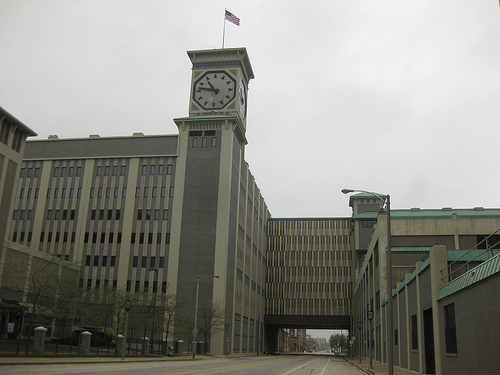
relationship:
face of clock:
[192, 72, 236, 112] [188, 49, 248, 131]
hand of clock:
[197, 86, 220, 93] [188, 49, 248, 131]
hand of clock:
[207, 81, 218, 94] [188, 49, 248, 131]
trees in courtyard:
[19, 256, 226, 354] [4, 332, 186, 364]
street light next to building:
[191, 273, 221, 361] [25, 139, 269, 357]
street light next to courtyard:
[191, 273, 221, 361] [4, 332, 186, 364]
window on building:
[137, 209, 143, 220] [25, 139, 269, 357]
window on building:
[139, 232, 146, 246] [25, 139, 269, 357]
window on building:
[148, 233, 154, 245] [25, 139, 269, 357]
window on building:
[155, 209, 161, 220] [25, 139, 269, 357]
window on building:
[143, 186, 149, 197] [25, 139, 269, 357]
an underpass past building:
[265, 323, 353, 357] [25, 139, 269, 357]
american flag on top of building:
[224, 10, 242, 26] [25, 139, 269, 357]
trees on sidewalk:
[19, 256, 226, 354] [1, 355, 203, 362]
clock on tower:
[188, 49, 248, 131] [163, 118, 246, 355]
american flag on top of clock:
[224, 10, 242, 26] [188, 49, 248, 131]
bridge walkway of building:
[264, 216, 357, 328] [25, 139, 269, 357]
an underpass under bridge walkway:
[265, 323, 353, 357] [264, 216, 357, 328]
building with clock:
[25, 139, 269, 357] [188, 49, 248, 131]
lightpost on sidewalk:
[191, 273, 221, 361] [1, 355, 203, 362]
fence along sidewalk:
[5, 331, 189, 356] [1, 355, 203, 362]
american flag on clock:
[224, 10, 242, 26] [188, 49, 248, 131]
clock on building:
[188, 49, 248, 131] [25, 139, 269, 357]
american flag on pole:
[224, 10, 242, 26] [221, 7, 227, 48]